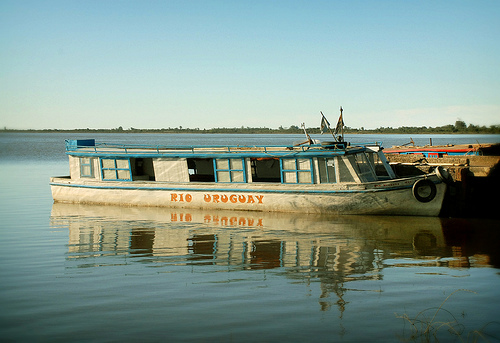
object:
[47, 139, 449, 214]
boat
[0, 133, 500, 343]
water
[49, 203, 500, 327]
reflection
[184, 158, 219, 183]
window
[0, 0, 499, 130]
sky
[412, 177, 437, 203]
life preserver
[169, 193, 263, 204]
writing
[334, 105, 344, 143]
flag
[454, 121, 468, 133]
tree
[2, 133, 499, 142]
shore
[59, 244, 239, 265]
ripple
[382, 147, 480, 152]
roof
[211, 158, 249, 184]
pane